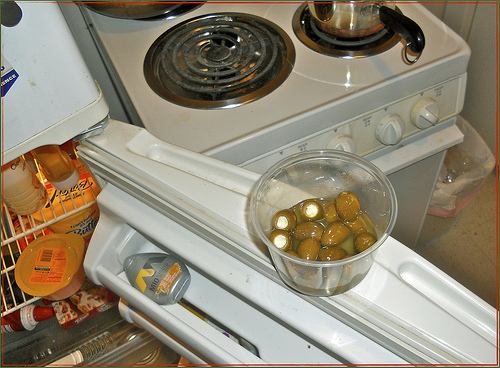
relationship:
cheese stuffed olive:
[306, 203, 319, 218] [274, 184, 365, 245]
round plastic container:
[219, 131, 413, 305] [247, 157, 384, 273]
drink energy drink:
[121, 250, 193, 306] [132, 229, 198, 297]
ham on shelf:
[30, 248, 81, 314] [27, 190, 71, 237]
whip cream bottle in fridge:
[12, 298, 42, 342] [2, 121, 170, 366]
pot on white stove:
[265, 6, 417, 67] [79, 4, 466, 191]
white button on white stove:
[346, 86, 441, 159] [277, 49, 467, 159]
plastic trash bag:
[433, 168, 466, 219] [453, 117, 484, 190]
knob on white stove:
[405, 87, 444, 144] [79, 4, 466, 191]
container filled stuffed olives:
[247, 157, 384, 273] [294, 190, 336, 223]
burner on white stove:
[135, 16, 279, 103] [79, 4, 466, 191]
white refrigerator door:
[27, 73, 69, 116] [43, 187, 464, 352]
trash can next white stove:
[479, 110, 492, 124] [79, 4, 466, 191]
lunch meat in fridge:
[17, 218, 92, 307] [0, 3, 493, 361]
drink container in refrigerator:
[121, 250, 193, 306] [2, 121, 170, 366]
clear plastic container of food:
[219, 131, 413, 305] [274, 184, 365, 245]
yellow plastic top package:
[17, 218, 92, 307] [13, 185, 120, 316]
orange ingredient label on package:
[20, 254, 62, 287] [13, 185, 120, 316]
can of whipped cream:
[3, 305, 55, 333] [11, 290, 53, 322]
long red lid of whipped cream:
[29, 303, 62, 327] [11, 290, 53, 322]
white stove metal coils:
[79, 4, 466, 191] [135, 16, 279, 103]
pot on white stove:
[303, 2, 425, 65] [79, 4, 466, 191]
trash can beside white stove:
[479, 110, 492, 124] [79, 4, 466, 191]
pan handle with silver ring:
[358, 11, 429, 81] [391, 23, 442, 74]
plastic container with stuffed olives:
[219, 131, 413, 305] [294, 190, 336, 223]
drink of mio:
[121, 250, 193, 306] [136, 257, 174, 299]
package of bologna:
[13, 185, 120, 316] [17, 218, 92, 307]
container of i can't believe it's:
[247, 157, 384, 273] [44, 184, 101, 251]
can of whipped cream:
[433, 120, 488, 213] [11, 290, 53, 322]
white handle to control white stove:
[302, 119, 359, 171] [79, 4, 466, 191]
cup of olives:
[219, 131, 413, 305] [274, 184, 365, 245]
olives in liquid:
[282, 194, 334, 236] [331, 227, 355, 251]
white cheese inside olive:
[271, 213, 298, 253] [274, 184, 365, 245]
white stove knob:
[27, 73, 69, 116] [405, 87, 444, 144]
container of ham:
[247, 157, 384, 273] [14, 233, 86, 303]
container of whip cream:
[247, 157, 384, 273] [12, 298, 42, 342]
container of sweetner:
[247, 157, 384, 273] [0, 145, 39, 209]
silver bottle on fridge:
[114, 244, 203, 338] [163, 143, 263, 266]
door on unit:
[76, 118, 494, 365] [120, 141, 308, 247]